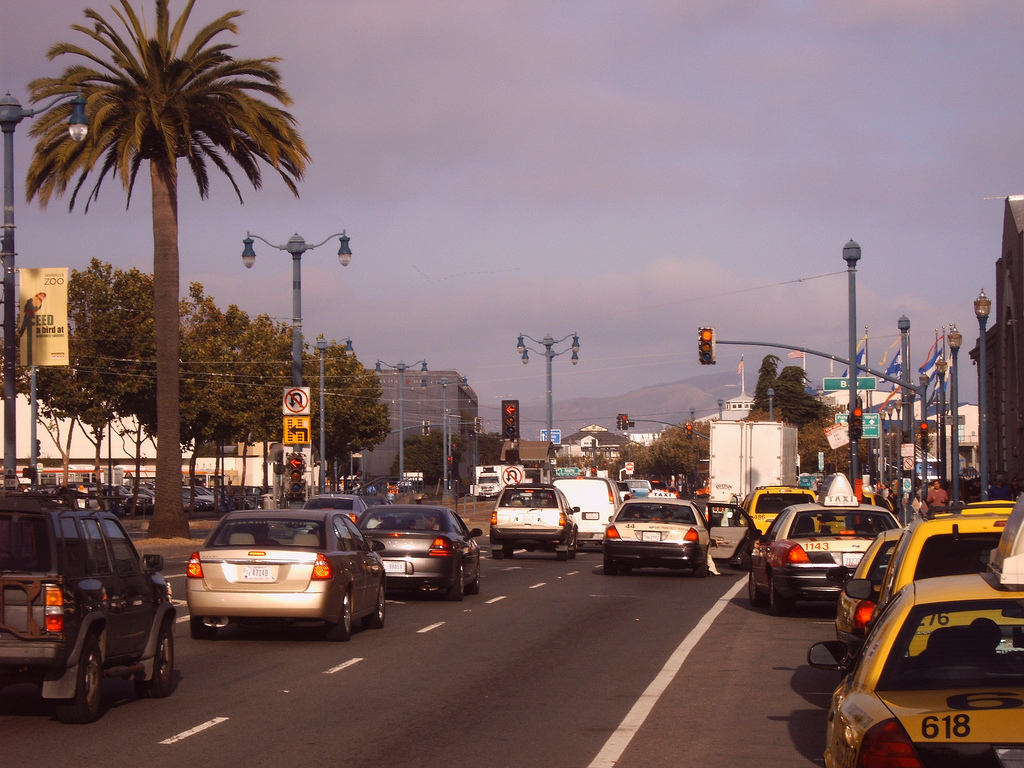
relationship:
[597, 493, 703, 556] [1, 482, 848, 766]
vehicle on road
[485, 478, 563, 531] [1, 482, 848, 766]
vehicle on road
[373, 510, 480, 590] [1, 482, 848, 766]
vehicle on road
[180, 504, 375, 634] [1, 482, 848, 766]
vehicle on road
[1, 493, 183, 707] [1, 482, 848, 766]
vehicle on road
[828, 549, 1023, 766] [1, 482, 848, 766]
taxi on road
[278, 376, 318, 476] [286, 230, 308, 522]
signs on pole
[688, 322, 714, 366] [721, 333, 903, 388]
light on pole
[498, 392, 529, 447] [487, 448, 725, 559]
light above vehicles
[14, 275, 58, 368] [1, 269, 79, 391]
bird on sign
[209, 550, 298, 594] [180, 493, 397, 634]
license plate on car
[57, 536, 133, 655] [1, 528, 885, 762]
car are on road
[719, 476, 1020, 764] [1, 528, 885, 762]
taxi cabs are on side of road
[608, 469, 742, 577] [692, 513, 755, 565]
car has door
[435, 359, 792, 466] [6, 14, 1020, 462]
mountain covered by clouds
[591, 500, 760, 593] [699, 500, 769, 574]
taxi has door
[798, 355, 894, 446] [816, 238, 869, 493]
street sign on poles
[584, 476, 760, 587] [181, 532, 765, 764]
taxi on lane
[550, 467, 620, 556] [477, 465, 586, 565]
van in front of suv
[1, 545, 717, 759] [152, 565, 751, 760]
lane road has lines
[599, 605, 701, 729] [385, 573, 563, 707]
line going down road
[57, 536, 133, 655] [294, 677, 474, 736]
car on road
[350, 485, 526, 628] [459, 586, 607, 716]
car on road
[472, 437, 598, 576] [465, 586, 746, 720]
car on road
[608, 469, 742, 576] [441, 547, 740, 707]
car on road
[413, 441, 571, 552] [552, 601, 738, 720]
car on road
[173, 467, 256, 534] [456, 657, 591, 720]
car on road